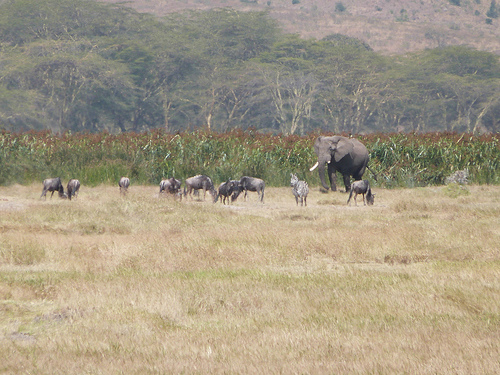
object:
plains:
[0, 182, 499, 374]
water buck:
[64, 179, 80, 201]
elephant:
[308, 134, 376, 192]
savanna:
[1, 0, 500, 375]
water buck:
[184, 174, 219, 205]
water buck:
[237, 176, 266, 201]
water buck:
[213, 179, 244, 204]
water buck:
[39, 177, 67, 201]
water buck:
[119, 176, 130, 196]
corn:
[0, 126, 500, 189]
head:
[208, 188, 217, 203]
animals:
[37, 135, 376, 209]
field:
[0, 0, 499, 375]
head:
[288, 172, 298, 188]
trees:
[0, 0, 499, 131]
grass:
[1, 0, 500, 375]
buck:
[344, 178, 376, 206]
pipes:
[290, 170, 310, 206]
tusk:
[309, 160, 331, 172]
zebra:
[287, 170, 310, 206]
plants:
[0, 128, 499, 191]